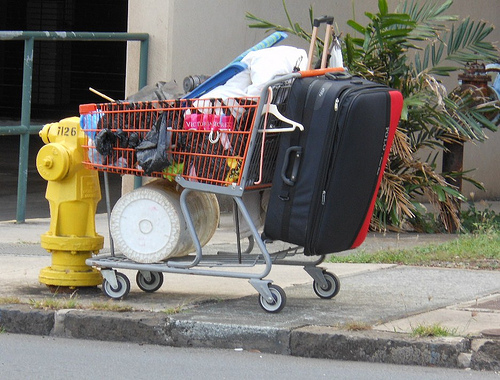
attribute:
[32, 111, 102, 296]
fire hydrant — yellow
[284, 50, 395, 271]
suitcase — black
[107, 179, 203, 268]
bucket — white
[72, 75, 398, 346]
buggy — orange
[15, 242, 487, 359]
sidewalk — paved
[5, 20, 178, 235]
railings — green, greeny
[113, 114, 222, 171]
plastic — black